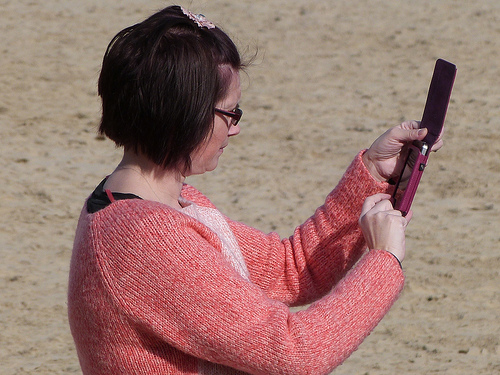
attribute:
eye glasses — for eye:
[206, 100, 245, 127]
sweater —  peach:
[83, 159, 478, 366]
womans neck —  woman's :
[117, 148, 191, 198]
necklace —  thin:
[111, 158, 173, 205]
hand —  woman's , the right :
[353, 187, 410, 264]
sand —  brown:
[2, 1, 499, 372]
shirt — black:
[91, 184, 126, 206]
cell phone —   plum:
[383, 53, 480, 210]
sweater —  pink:
[62, 147, 414, 373]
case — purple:
[374, 162, 431, 226]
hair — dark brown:
[88, 22, 240, 179]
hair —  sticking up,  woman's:
[140, 32, 225, 97]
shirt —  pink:
[187, 199, 259, 276]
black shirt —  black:
[79, 179, 148, 213]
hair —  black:
[96, 3, 216, 178]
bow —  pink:
[179, 5, 221, 31]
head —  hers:
[93, 7, 243, 173]